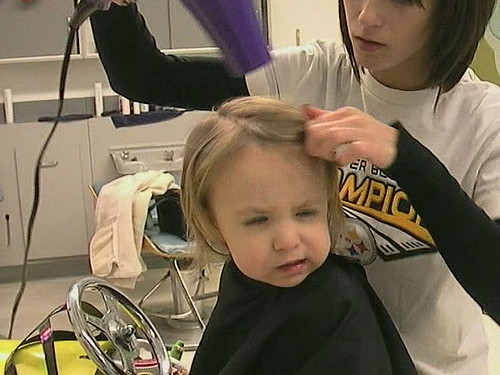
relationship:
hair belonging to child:
[179, 92, 359, 282] [176, 96, 418, 375]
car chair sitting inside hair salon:
[1, 274, 188, 373] [1, 1, 484, 371]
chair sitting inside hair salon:
[86, 175, 216, 331] [1, 1, 484, 371]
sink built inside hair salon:
[111, 147, 194, 173] [1, 1, 484, 371]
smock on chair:
[183, 256, 418, 372] [81, 168, 243, 335]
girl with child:
[85, 0, 496, 373] [176, 96, 418, 375]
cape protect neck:
[199, 240, 419, 375] [378, 105, 379, 111]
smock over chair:
[90, 171, 180, 289] [80, 168, 226, 336]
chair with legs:
[77, 175, 217, 331] [143, 266, 224, 316]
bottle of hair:
[3, 88, 15, 123] [161, 103, 364, 278]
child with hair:
[176, 96, 418, 375] [162, 117, 359, 267]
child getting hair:
[176, 96, 418, 375] [145, 85, 365, 282]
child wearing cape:
[176, 96, 418, 375] [182, 232, 419, 375]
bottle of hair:
[3, 82, 26, 125] [165, 98, 346, 267]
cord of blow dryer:
[11, 67, 79, 353] [187, 98, 213, 114]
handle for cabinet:
[35, 160, 67, 169] [16, 140, 93, 252]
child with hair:
[176, 96, 418, 375] [166, 119, 352, 289]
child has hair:
[149, 120, 445, 375] [158, 78, 360, 259]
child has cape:
[176, 96, 418, 375] [188, 251, 419, 372]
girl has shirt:
[85, 0, 484, 373] [242, 36, 483, 373]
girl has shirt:
[85, 0, 484, 373] [83, 1, 253, 113]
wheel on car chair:
[64, 272, 174, 372] [0, 274, 187, 375]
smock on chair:
[90, 171, 180, 289] [86, 175, 216, 331]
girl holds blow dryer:
[85, 0, 484, 373] [68, 0, 270, 74]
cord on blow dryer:
[8, 30, 76, 353] [68, 0, 270, 74]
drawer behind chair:
[12, 145, 90, 261] [86, 175, 216, 331]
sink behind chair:
[104, 139, 194, 173] [86, 175, 216, 331]